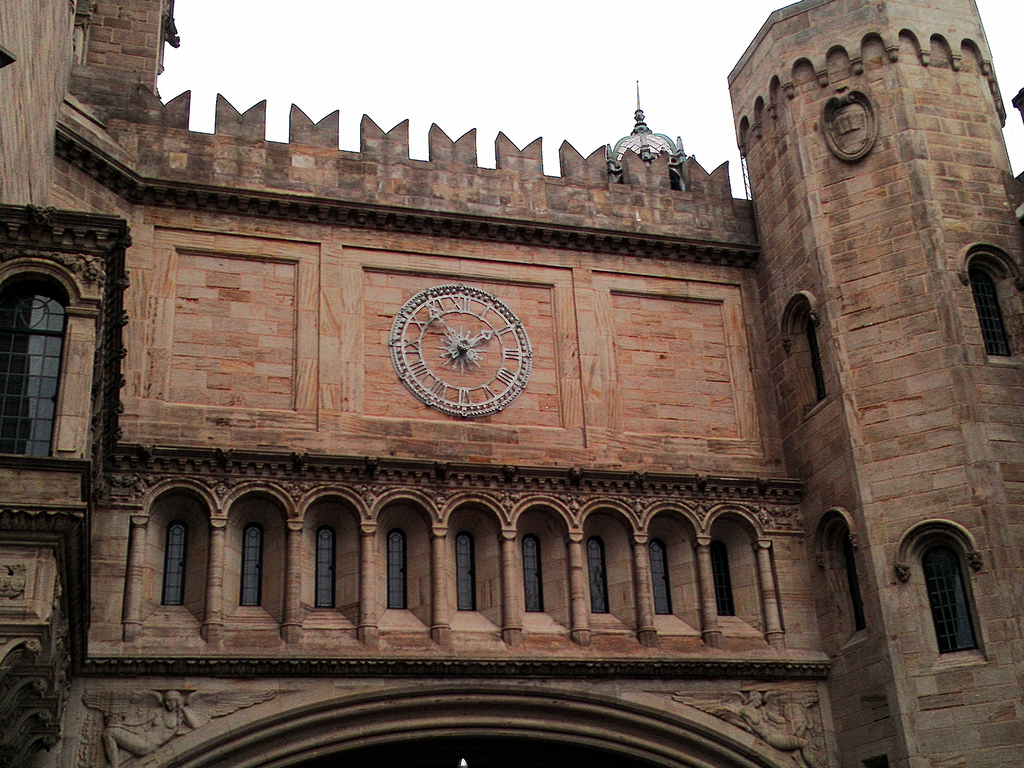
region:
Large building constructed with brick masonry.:
[4, 0, 1020, 767]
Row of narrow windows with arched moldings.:
[89, 472, 814, 651]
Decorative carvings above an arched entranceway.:
[67, 664, 837, 762]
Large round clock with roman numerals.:
[386, 277, 534, 417]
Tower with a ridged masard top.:
[724, 0, 1022, 767]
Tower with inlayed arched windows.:
[727, 0, 1018, 763]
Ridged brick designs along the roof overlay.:
[39, 77, 747, 252]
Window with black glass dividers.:
[4, 280, 62, 449]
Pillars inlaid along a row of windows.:
[92, 444, 816, 653]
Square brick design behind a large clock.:
[128, 212, 770, 468]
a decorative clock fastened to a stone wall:
[389, 285, 530, 418]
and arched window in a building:
[513, 500, 575, 640]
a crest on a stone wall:
[817, 86, 887, 167]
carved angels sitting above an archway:
[78, 676, 834, 766]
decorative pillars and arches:
[121, 478, 780, 644]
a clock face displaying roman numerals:
[390, 287, 533, 414]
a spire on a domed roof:
[598, 79, 685, 171]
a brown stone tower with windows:
[741, 6, 1004, 765]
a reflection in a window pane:
[912, 533, 982, 664]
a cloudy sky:
[426, 32, 553, 121]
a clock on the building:
[397, 276, 543, 420]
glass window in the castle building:
[378, 522, 407, 617]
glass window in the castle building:
[450, 529, 470, 615]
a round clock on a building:
[386, 275, 535, 416]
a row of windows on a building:
[136, 499, 759, 642]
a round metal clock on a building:
[390, 267, 531, 416]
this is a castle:
[48, 76, 845, 683]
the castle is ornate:
[135, 74, 639, 376]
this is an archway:
[102, 437, 894, 758]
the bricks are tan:
[155, 215, 568, 573]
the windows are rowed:
[207, 469, 771, 713]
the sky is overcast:
[304, 32, 614, 153]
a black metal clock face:
[384, 279, 536, 415]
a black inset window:
[881, 513, 1012, 666]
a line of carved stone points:
[153, 88, 754, 200]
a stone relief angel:
[77, 681, 300, 764]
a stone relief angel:
[666, 685, 832, 765]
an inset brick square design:
[584, 265, 768, 458]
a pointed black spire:
[599, 74, 689, 164]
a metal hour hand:
[453, 324, 499, 359]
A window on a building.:
[157, 513, 192, 611]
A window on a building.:
[233, 525, 285, 627]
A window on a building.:
[310, 517, 342, 603]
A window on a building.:
[379, 522, 415, 611]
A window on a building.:
[457, 526, 486, 621]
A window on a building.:
[522, 529, 542, 612]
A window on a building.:
[713, 533, 753, 622]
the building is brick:
[157, 150, 831, 651]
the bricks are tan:
[127, 206, 744, 617]